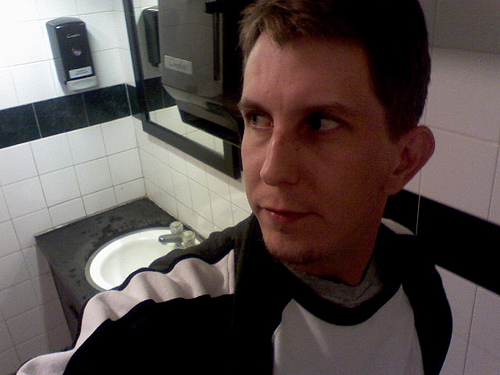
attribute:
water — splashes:
[89, 220, 108, 234]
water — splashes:
[59, 218, 127, 234]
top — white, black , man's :
[27, 222, 457, 371]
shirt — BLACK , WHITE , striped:
[11, 213, 455, 371]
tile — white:
[67, 156, 115, 196]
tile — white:
[421, 43, 498, 142]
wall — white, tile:
[128, 7, 498, 372]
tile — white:
[100, 113, 137, 153]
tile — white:
[65, 124, 109, 163]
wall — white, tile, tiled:
[2, 0, 147, 374]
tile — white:
[28, 132, 74, 177]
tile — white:
[0, 142, 46, 187]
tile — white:
[102, 147, 144, 188]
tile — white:
[72, 157, 114, 197]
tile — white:
[38, 164, 85, 206]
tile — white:
[2, 174, 50, 217]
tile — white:
[115, 177, 146, 207]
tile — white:
[78, 185, 120, 215]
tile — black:
[32, 94, 92, 141]